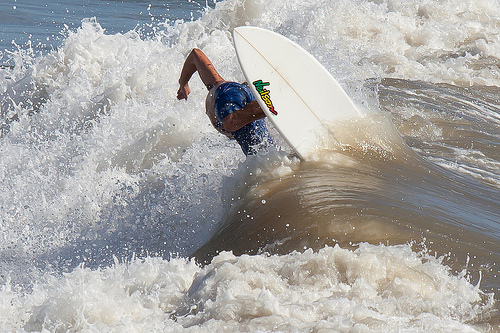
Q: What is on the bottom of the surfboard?
A: Lettering.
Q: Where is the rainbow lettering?
A: On the surfboard.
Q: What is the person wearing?
A: Swimsuit.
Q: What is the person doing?
A: Surfing.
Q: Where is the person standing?
A: On surfboard.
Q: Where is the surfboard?
A: In the ocean.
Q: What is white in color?
A: The splash.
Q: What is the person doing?
A: Surfing.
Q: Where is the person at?
A: Beach.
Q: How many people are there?
A: One.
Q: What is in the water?
A: Surfboard.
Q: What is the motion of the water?
A: Wavy.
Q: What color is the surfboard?
A: White.